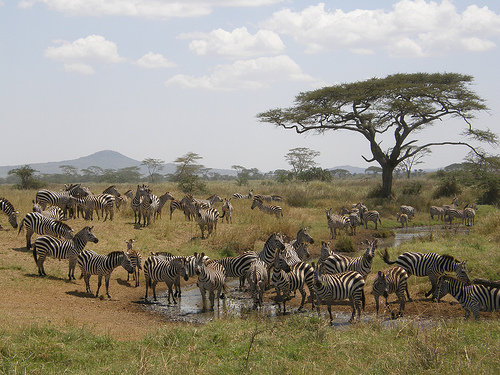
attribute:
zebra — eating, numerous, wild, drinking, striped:
[141, 255, 191, 307]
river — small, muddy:
[145, 212, 472, 330]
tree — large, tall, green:
[253, 71, 500, 197]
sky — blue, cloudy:
[1, 2, 499, 173]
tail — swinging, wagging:
[377, 245, 397, 266]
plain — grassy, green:
[2, 188, 334, 373]